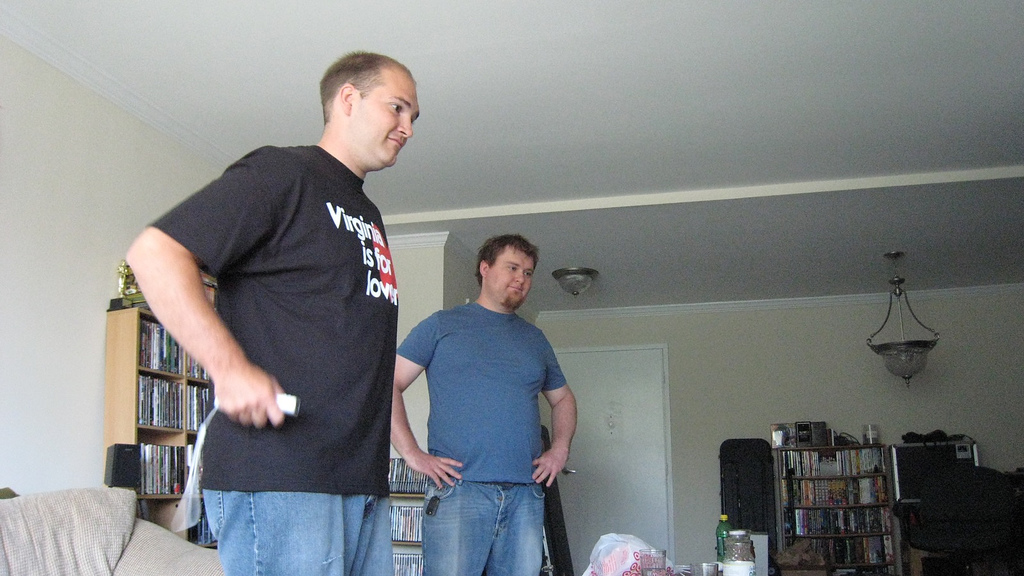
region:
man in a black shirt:
[111, 50, 425, 569]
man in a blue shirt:
[403, 225, 591, 571]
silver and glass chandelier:
[858, 240, 948, 400]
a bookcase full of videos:
[765, 414, 895, 573]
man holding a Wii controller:
[125, 47, 423, 573]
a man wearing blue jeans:
[118, 45, 406, 573]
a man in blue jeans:
[399, 230, 584, 573]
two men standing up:
[128, 38, 584, 571]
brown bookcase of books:
[102, 285, 214, 548]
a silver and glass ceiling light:
[548, 258, 606, 304]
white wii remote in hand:
[201, 390, 309, 420]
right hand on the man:
[201, 372, 297, 440]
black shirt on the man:
[155, 138, 411, 502]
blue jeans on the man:
[204, 485, 394, 572]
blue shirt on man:
[403, 296, 566, 489]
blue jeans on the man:
[420, 483, 557, 570]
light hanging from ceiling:
[852, 280, 963, 401]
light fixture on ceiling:
[546, 262, 603, 301]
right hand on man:
[398, 453, 468, 498]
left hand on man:
[524, 442, 575, 484]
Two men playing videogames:
[110, 50, 643, 569]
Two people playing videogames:
[123, 45, 659, 570]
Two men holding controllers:
[108, 40, 634, 569]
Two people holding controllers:
[123, 40, 626, 566]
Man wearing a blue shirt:
[408, 215, 601, 561]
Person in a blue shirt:
[408, 215, 608, 563]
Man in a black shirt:
[110, 18, 466, 563]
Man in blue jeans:
[410, 195, 594, 566]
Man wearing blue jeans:
[130, 35, 451, 570]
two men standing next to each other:
[90, 19, 613, 552]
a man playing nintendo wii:
[119, 37, 443, 547]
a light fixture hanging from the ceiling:
[848, 231, 948, 400]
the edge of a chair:
[4, 424, 249, 568]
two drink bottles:
[705, 503, 763, 570]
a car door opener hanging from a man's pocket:
[406, 477, 457, 534]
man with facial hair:
[478, 231, 551, 330]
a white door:
[514, 319, 699, 567]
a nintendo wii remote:
[143, 379, 315, 541]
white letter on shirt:
[320, 195, 346, 234]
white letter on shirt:
[338, 210, 351, 229]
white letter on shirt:
[346, 211, 356, 232]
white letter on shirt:
[349, 216, 365, 242]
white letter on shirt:
[358, 239, 369, 268]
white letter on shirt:
[364, 245, 375, 266]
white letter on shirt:
[368, 244, 382, 273]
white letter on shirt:
[374, 254, 394, 275]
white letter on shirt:
[360, 267, 374, 297]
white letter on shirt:
[361, 268, 385, 303]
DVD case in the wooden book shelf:
[146, 318, 157, 372]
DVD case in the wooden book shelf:
[137, 371, 145, 429]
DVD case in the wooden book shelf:
[146, 368, 153, 429]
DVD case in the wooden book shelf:
[150, 375, 157, 418]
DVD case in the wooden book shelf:
[160, 381, 162, 427]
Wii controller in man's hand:
[196, 376, 302, 425]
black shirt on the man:
[151, 138, 401, 503]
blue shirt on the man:
[398, 303, 572, 487]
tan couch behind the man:
[3, 486, 235, 573]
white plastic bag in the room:
[582, 519, 668, 573]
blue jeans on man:
[427, 473, 549, 573]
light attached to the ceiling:
[552, 260, 600, 299]